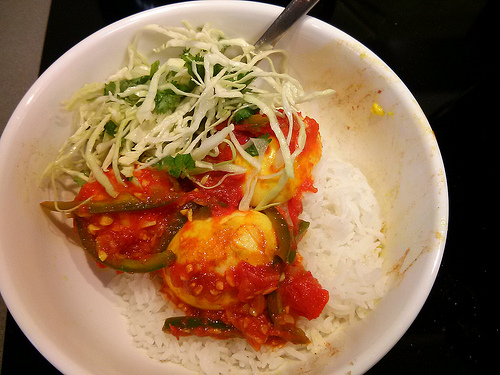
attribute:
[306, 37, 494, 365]
plate — white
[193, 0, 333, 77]
utensil — silver.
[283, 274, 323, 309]
tomato sauce — red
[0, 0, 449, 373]
plate — white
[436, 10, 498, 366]
black mat — black..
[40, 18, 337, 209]
garnish — white, green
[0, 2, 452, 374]
bowl — white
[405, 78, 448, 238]
plate — piece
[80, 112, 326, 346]
sauce — red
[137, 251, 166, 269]
pepper — green